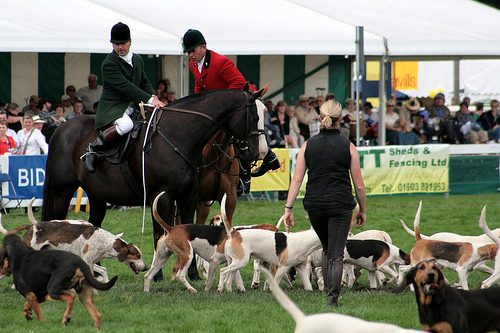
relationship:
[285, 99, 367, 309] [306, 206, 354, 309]
woman wearing pants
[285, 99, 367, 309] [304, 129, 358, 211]
woman wearing shirt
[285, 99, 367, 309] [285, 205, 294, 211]
woman wearing bracelet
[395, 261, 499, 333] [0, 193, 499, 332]
dog on ground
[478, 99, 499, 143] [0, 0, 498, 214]
spectator in stand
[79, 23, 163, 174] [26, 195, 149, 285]
man looking at dog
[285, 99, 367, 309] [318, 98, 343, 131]
woman has hair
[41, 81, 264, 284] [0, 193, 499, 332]
horse on ground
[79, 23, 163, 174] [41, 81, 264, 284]
man on horse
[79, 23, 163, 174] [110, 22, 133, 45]
man wearing hat